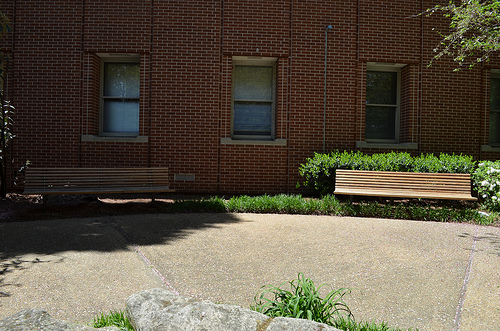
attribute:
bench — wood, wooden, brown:
[21, 163, 175, 210]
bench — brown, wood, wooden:
[331, 165, 479, 209]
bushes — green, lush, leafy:
[296, 146, 475, 197]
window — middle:
[231, 63, 272, 136]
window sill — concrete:
[82, 131, 148, 143]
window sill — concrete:
[220, 134, 286, 147]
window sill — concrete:
[353, 139, 419, 149]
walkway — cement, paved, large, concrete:
[2, 213, 498, 331]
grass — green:
[170, 195, 490, 227]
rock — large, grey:
[84, 287, 346, 329]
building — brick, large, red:
[1, 1, 497, 193]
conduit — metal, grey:
[320, 22, 334, 155]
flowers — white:
[478, 161, 499, 205]